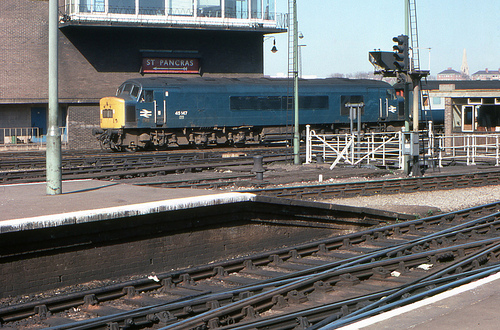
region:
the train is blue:
[94, 74, 420, 133]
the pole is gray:
[34, 25, 65, 207]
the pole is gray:
[37, 12, 87, 221]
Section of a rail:
[126, 115, 256, 207]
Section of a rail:
[269, 190, 389, 307]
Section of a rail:
[121, 219, 236, 305]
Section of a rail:
[281, 239, 398, 323]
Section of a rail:
[264, 123, 339, 204]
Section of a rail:
[78, 148, 197, 218]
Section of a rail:
[0, 134, 41, 202]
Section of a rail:
[360, 220, 471, 315]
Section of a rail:
[234, 245, 336, 325]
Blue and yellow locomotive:
[104, 59, 401, 142]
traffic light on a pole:
[386, 34, 413, 80]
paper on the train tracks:
[383, 252, 445, 286]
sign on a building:
[138, 46, 204, 80]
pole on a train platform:
[43, 25, 66, 199]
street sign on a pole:
[390, 80, 412, 104]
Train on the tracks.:
[94, 72, 441, 154]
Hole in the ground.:
[2, 195, 395, 327]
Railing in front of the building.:
[0, 124, 44, 149]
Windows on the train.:
[116, 80, 155, 104]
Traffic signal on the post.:
[367, 33, 420, 89]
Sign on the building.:
[132, 48, 207, 78]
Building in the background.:
[0, 0, 287, 147]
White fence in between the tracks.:
[300, 123, 497, 174]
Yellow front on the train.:
[95, 92, 125, 130]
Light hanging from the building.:
[265, 35, 282, 57]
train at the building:
[77, 65, 408, 147]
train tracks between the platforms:
[143, 225, 481, 302]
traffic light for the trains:
[391, 30, 407, 77]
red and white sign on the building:
[136, 42, 205, 77]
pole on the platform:
[33, 8, 77, 200]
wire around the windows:
[67, 10, 284, 31]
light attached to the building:
[265, 30, 284, 53]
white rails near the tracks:
[313, 123, 425, 171]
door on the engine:
[148, 88, 164, 125]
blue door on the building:
[26, 105, 51, 148]